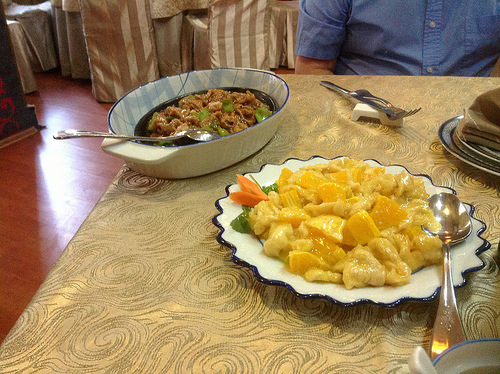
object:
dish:
[211, 156, 494, 309]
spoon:
[421, 192, 474, 361]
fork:
[319, 80, 421, 119]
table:
[44, 302, 315, 374]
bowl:
[101, 67, 292, 180]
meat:
[167, 114, 188, 131]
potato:
[350, 208, 389, 241]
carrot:
[229, 174, 269, 208]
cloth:
[73, 244, 216, 371]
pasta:
[257, 227, 306, 251]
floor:
[5, 196, 70, 244]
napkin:
[456, 87, 500, 152]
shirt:
[296, 9, 500, 77]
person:
[294, 3, 500, 77]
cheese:
[294, 186, 378, 237]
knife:
[350, 94, 402, 121]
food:
[133, 80, 446, 294]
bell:
[211, 99, 274, 134]